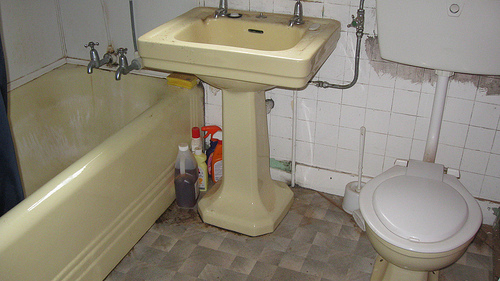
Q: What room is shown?
A: It is a bathroom.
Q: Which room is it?
A: It is a bathroom.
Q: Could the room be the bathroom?
A: Yes, it is the bathroom.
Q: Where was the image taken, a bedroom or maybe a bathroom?
A: It was taken at a bathroom.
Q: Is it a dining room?
A: No, it is a bathroom.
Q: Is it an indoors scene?
A: Yes, it is indoors.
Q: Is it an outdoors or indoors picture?
A: It is indoors.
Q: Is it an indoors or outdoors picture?
A: It is indoors.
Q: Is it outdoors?
A: No, it is indoors.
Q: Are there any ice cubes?
A: No, there are no ice cubes.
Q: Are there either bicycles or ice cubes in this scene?
A: No, there are no ice cubes or bicycles.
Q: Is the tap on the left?
A: Yes, the tap is on the left of the image.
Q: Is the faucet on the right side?
A: No, the faucet is on the left of the image.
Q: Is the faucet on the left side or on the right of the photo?
A: The faucet is on the left of the image.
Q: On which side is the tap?
A: The tap is on the left of the image.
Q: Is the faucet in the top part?
A: Yes, the faucet is in the top of the image.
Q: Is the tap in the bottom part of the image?
A: No, the tap is in the top of the image.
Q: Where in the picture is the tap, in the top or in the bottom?
A: The tap is in the top of the image.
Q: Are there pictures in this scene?
A: No, there are no pictures.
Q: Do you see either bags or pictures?
A: No, there are no pictures or bags.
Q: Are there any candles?
A: No, there are no candles.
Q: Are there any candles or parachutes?
A: No, there are no candles or parachutes.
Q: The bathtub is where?
A: The bathtub is in the bathroom.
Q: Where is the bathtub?
A: The bathtub is in the bathroom.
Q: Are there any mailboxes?
A: No, there are no mailboxes.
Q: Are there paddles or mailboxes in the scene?
A: No, there are no mailboxes or paddles.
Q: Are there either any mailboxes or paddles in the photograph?
A: No, there are no mailboxes or paddles.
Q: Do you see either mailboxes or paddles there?
A: No, there are no mailboxes or paddles.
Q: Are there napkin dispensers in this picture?
A: No, there are no napkin dispensers.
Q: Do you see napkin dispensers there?
A: No, there are no napkin dispensers.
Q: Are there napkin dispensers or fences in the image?
A: No, there are no napkin dispensers or fences.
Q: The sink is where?
A: The sink is in the bathroom.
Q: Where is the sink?
A: The sink is in the bathroom.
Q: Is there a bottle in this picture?
A: Yes, there is a bottle.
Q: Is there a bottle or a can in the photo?
A: Yes, there is a bottle.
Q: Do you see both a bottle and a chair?
A: No, there is a bottle but no chairs.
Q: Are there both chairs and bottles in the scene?
A: No, there is a bottle but no chairs.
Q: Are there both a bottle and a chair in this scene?
A: No, there is a bottle but no chairs.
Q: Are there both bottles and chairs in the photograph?
A: No, there is a bottle but no chairs.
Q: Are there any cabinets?
A: No, there are no cabinets.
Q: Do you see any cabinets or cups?
A: No, there are no cabinets or cups.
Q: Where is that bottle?
A: The bottle is on the floor.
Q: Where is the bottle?
A: The bottle is on the floor.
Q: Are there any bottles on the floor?
A: Yes, there is a bottle on the floor.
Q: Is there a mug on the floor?
A: No, there is a bottle on the floor.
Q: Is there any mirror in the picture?
A: No, there are no mirrors.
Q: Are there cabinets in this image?
A: No, there are no cabinets.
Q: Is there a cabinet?
A: No, there are no cabinets.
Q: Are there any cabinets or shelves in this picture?
A: No, there are no cabinets or shelves.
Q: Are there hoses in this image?
A: No, there are no hoses.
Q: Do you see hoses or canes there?
A: No, there are no hoses or canes.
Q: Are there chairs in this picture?
A: No, there are no chairs.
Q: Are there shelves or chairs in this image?
A: No, there are no chairs or shelves.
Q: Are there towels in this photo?
A: No, there are no towels.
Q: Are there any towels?
A: No, there are no towels.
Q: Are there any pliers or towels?
A: No, there are no towels or pliers.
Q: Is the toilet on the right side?
A: Yes, the toilet is on the right of the image.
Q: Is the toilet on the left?
A: No, the toilet is on the right of the image.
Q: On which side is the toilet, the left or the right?
A: The toilet is on the right of the image.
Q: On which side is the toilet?
A: The toilet is on the right of the image.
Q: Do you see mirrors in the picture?
A: No, there are no mirrors.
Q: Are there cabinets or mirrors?
A: No, there are no mirrors or cabinets.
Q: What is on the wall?
A: The tiles are on the wall.